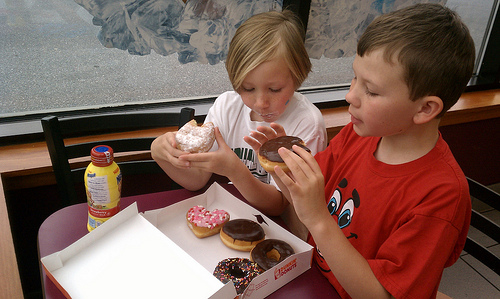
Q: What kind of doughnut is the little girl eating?
A: White powdered.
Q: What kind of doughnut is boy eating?
A: Chocolate frosted.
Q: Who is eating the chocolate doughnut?
A: The little boy.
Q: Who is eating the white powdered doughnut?
A: The little girl.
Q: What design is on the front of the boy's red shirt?
A: 2 big eyes.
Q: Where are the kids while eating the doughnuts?
A: Sitting at the table.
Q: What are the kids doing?
A: Eating.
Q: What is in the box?
A: Doughnuts.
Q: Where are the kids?
A: At the table.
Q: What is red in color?
A: The shirt.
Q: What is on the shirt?
A: A face.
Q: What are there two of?
A: Kids.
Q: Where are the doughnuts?
A: In a box.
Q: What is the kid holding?
A: The doughnut.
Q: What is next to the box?
A: A drink.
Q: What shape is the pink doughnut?
A: Heart.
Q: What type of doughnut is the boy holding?
A: Chocolate.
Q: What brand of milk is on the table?
A: Nesquik.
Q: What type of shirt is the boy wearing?
A: Red t shirt.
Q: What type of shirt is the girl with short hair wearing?
A: White t shirt.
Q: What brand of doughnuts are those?
A: Dunkin Donuts.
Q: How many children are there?
A: 2.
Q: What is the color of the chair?
A: Black.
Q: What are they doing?
A: Eating.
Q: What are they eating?
A: Donut.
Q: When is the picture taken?
A: Daytime.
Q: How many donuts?
A: 6.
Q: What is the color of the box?
A: White.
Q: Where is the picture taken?
A: At a donut shop.